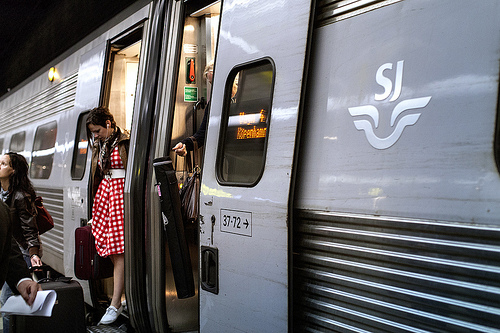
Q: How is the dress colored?
A: Red and white.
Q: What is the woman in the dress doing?
A: Stepping off the train.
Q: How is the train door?
A: Open.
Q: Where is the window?
A: On the door and sides of the train.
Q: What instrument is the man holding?
A: Violin.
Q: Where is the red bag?
A: On the woman's shoulder.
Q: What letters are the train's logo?
A: SJ.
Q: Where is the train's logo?
A: On the side.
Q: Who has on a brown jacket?
A: A woman has on a brown jacket.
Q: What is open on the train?
A: The door is open on the train.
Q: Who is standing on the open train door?
A: A woman is standing on an open train door.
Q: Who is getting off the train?
A: A woman.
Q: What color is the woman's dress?
A: Red and white.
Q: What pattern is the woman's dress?
A: Checkered.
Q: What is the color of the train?
A: Gray.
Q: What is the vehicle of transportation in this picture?
A: A train.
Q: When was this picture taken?
A: Nighttime.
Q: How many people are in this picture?
A: Two.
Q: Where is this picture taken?
A: A train station.